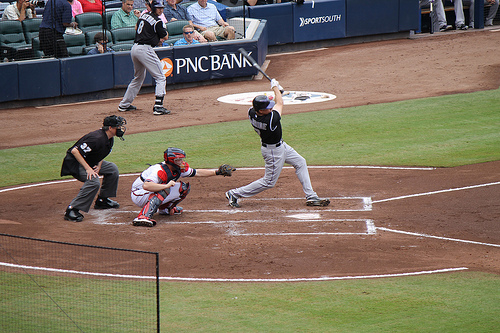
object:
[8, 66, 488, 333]
game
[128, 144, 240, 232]
catcher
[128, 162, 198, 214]
white uniform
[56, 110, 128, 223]
referee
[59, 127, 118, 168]
black shirt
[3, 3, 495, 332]
photo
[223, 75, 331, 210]
batter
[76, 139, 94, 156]
37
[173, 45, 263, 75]
pnc bank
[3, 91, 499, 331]
green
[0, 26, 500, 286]
dirt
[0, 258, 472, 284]
white lines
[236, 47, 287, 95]
bat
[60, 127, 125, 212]
dark clothing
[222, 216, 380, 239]
rectangles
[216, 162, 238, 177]
black mitt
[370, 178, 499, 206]
line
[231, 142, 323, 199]
pants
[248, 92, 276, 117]
helmet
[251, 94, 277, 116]
head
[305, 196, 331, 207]
twisted foot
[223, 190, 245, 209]
foot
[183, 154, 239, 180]
front of him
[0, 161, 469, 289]
oval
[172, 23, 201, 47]
fan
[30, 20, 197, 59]
first row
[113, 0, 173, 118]
player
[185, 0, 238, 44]
fans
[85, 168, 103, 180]
hand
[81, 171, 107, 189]
knee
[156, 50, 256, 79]
sign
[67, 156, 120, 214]
gray pants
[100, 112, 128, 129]
black hat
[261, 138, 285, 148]
black belt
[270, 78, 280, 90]
white glove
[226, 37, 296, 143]
to strike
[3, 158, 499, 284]
turf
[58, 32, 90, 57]
chairs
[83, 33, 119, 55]
audience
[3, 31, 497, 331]
field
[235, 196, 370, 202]
lines